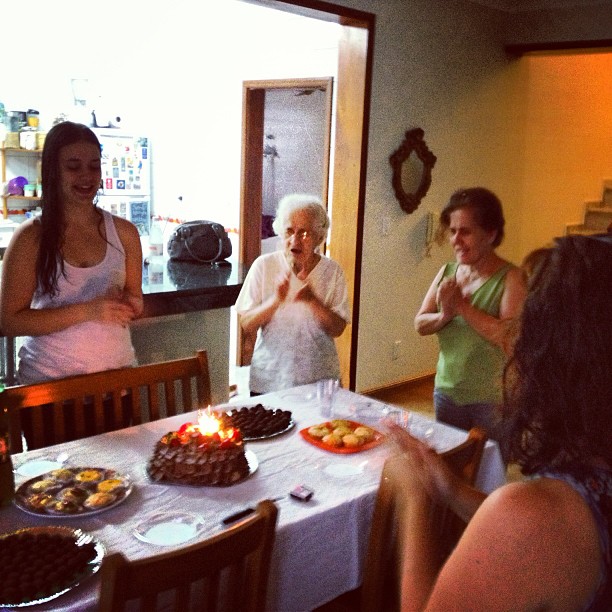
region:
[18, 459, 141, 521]
a plate made for dining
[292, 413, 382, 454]
a plate made for dining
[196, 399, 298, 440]
a plate made for dining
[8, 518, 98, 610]
a plate made for dining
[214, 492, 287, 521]
a utensil made for dining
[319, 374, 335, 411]
a vessel made for drinking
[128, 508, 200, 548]
a plate made for dining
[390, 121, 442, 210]
a picture in a frame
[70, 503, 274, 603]
a chair that you sit in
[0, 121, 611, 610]
the people are standing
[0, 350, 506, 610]
the bench and chairs around the table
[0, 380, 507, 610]
the tablecloth is white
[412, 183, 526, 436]
the woman wearing a green top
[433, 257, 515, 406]
the top is green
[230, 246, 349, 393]
the shirt is white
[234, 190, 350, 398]
the elderly woman wearing a white shirt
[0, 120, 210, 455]
the young woman standing in front of the bench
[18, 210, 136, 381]
the tanktop is white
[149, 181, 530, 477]
Two women with birthday cake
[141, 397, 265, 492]
Birthday cake with candle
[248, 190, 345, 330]
old woman clapping hands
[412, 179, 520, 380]
woman clapping her hands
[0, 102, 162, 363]
smiling woman wearing a tank top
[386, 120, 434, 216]
mirror hanging on wall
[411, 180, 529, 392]
Woman holding her hands together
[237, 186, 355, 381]
gray haired woman clapping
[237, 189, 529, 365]
two women clapping hands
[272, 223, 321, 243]
a woman wearing glasses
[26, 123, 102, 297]
a woman with long hair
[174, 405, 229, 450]
a candle on top of a cake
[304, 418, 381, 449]
a red plate with cookies on it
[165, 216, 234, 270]
a purse on a counter top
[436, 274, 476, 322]
a woman holding her hands together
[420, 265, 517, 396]
a woman wearing a green shirt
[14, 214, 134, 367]
a woman wearing a white shirt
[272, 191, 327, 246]
a woman with white hair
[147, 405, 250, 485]
a chocolate cake with strawberries and lit candles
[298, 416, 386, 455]
a square red plate with an assortment of pastries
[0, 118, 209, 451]
a woman with long hair standing in front of two chairs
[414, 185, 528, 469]
woamn with a green tank top is clapping her hands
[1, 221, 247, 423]
a black purse sits on top of a kitchen island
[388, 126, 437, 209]
a mirror with a wooden frame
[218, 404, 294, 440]
a silver plate full of chocolate truffles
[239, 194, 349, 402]
an old woman with white hair wearing glasses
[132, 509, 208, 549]
an empty small white plate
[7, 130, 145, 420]
a person is standing up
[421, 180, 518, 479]
a person is standing up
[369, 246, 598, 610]
a person is standing up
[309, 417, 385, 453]
a plate made for dining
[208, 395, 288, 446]
a plate made for dining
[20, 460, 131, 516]
a plate made for dining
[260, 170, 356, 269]
woman has white hair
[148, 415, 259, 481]
cake is on table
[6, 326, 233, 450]
brown chair in front of woman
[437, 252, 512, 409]
woman has green shirt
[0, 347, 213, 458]
a long brown bench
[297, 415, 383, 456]
a large red plate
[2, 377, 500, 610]
a white tablecloth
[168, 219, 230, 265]
a large black purse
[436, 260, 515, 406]
a woman's green tank top